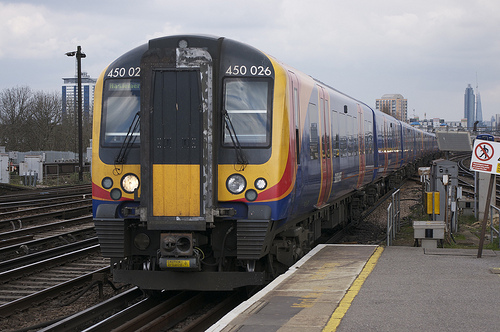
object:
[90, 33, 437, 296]
train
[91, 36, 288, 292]
train front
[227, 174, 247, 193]
headlight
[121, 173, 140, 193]
headlight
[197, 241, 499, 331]
platform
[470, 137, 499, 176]
sign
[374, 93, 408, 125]
building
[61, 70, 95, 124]
building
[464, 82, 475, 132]
building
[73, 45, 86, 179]
electric pole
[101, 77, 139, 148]
window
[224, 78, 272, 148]
window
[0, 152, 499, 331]
tracks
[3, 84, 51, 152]
trees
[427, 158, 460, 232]
electrical box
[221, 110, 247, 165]
windshield wiper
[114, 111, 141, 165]
windshield wiper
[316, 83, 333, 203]
doors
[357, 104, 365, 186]
doors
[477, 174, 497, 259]
pole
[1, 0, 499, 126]
sky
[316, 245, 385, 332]
stripe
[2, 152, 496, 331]
ground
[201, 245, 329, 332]
line